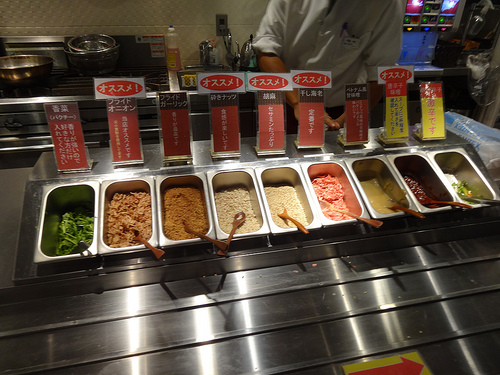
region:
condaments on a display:
[35, 25, 499, 279]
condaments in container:
[11, 41, 499, 286]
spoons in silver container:
[26, 125, 496, 255]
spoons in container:
[12, 95, 499, 265]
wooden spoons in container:
[23, 138, 498, 282]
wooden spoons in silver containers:
[27, 151, 483, 273]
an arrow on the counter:
[314, 309, 463, 374]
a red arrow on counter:
[322, 341, 432, 374]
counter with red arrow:
[310, 318, 468, 373]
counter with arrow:
[326, 318, 446, 374]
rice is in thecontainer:
[274, 174, 308, 232]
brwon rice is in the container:
[165, 192, 218, 257]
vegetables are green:
[54, 205, 101, 275]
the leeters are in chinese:
[206, 108, 319, 142]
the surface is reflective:
[208, 307, 333, 372]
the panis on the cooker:
[7, 48, 57, 80]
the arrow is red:
[346, 337, 433, 373]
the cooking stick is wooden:
[130, 229, 176, 267]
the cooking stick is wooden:
[278, 203, 314, 240]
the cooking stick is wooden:
[393, 198, 424, 228]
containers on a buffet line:
[27, 145, 499, 265]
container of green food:
[37, 175, 138, 235]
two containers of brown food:
[96, 172, 205, 262]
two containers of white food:
[210, 164, 298, 242]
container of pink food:
[310, 160, 357, 233]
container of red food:
[393, 148, 461, 226]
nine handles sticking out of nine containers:
[40, 187, 492, 267]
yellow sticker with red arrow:
[345, 343, 432, 373]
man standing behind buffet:
[252, 5, 420, 115]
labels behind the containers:
[30, 56, 453, 143]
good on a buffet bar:
[30, 137, 498, 288]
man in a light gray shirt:
[253, 0, 408, 129]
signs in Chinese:
[27, 50, 490, 172]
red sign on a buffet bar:
[31, 87, 103, 182]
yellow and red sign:
[416, 70, 448, 147]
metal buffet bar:
[3, 200, 496, 373]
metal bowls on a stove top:
[54, 22, 123, 76]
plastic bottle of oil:
[161, 20, 187, 74]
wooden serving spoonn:
[214, 211, 251, 264]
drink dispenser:
[403, 0, 459, 70]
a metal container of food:
[33, 180, 98, 265]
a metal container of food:
[100, 171, 155, 256]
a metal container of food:
[152, 166, 212, 246]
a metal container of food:
[205, 161, 270, 238]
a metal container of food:
[250, 160, 317, 240]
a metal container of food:
[296, 160, 368, 226]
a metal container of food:
[340, 151, 415, 216]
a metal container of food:
[385, 150, 460, 215]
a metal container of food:
[422, 145, 497, 206]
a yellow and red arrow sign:
[342, 345, 432, 372]